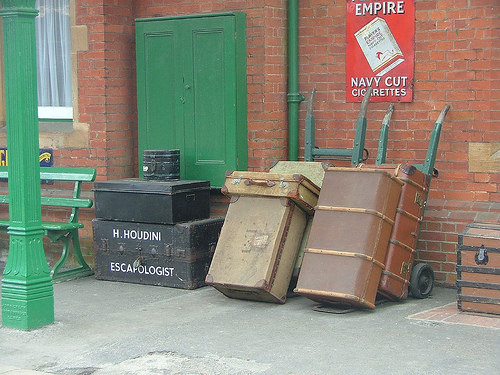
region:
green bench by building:
[37, 154, 93, 290]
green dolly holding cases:
[375, 97, 469, 311]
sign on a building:
[338, 1, 424, 111]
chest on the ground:
[456, 220, 498, 330]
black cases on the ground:
[83, 154, 218, 299]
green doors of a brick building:
[128, 4, 250, 186]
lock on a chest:
[471, 244, 491, 272]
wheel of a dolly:
[406, 257, 438, 300]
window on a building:
[33, 0, 83, 136]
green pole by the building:
[3, 55, 67, 332]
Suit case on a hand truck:
[309, 129, 430, 321]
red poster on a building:
[342, 0, 417, 103]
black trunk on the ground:
[87, 214, 204, 294]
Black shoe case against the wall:
[88, 177, 187, 232]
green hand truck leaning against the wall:
[374, 97, 452, 167]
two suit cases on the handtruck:
[311, 153, 433, 317]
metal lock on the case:
[468, 247, 489, 267]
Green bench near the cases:
[48, 155, 95, 286]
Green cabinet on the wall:
[131, 8, 243, 197]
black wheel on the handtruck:
[404, 260, 436, 298]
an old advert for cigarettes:
[339, 0, 419, 107]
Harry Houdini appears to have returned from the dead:
[85, 208, 230, 295]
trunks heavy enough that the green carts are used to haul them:
[291, 85, 457, 320]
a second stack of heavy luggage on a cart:
[196, 76, 383, 309]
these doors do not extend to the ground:
[125, 8, 255, 195]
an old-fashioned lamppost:
[1, 1, 66, 334]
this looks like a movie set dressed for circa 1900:
[2, 2, 497, 344]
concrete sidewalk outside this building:
[53, 269, 454, 374]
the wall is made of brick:
[300, 0, 499, 285]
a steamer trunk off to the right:
[450, 220, 499, 320]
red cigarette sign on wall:
[335, 0, 431, 105]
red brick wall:
[443, 60, 498, 123]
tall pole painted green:
[0, 8, 50, 330]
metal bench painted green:
[1, 158, 96, 273]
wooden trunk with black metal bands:
[448, 206, 498, 328]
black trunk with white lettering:
[83, 213, 210, 293]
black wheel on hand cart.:
[404, 244, 438, 319]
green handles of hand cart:
[293, 78, 367, 163]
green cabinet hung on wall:
[128, 11, 256, 188]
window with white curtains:
[3, 0, 88, 145]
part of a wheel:
[418, 273, 428, 290]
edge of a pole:
[326, 146, 334, 166]